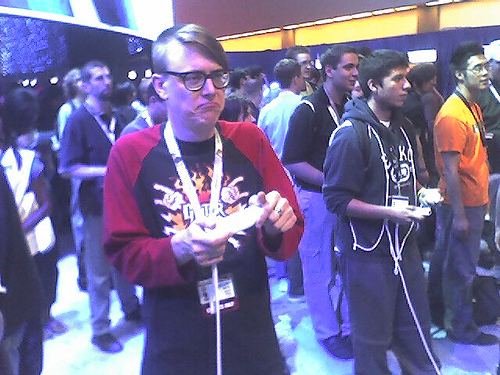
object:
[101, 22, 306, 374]
man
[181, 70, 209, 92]
glasses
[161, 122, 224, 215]
lanyard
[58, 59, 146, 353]
man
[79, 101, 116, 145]
lanyard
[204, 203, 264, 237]
controller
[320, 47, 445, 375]
man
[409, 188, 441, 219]
controller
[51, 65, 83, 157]
people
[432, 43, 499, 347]
man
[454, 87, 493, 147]
camera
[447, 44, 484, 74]
hair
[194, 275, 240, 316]
tag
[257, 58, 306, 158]
man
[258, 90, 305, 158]
shirt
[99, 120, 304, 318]
shirt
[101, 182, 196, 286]
sleeves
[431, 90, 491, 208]
shirt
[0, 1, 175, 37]
light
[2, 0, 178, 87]
wall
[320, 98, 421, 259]
hoodie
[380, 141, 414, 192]
print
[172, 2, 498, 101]
wall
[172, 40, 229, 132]
face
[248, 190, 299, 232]
hands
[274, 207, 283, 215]
ring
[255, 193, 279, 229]
finger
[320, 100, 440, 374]
clothing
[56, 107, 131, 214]
shirt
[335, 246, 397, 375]
pants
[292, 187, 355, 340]
pants